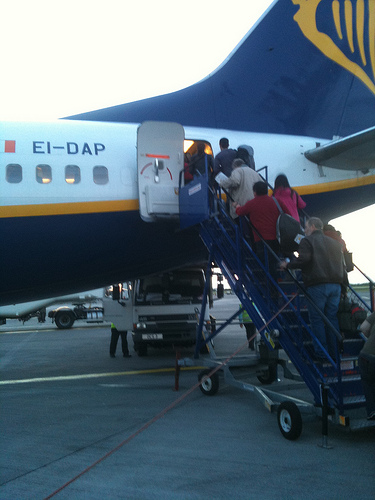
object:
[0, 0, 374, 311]
plane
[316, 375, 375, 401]
stairs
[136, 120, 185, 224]
door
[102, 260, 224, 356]
truck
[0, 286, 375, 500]
tarmac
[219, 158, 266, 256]
passenger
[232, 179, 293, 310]
person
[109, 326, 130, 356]
pants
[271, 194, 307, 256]
bag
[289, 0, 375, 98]
logo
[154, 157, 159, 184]
handle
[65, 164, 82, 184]
window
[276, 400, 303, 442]
wheel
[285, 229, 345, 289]
jacket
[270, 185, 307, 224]
coat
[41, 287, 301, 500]
cord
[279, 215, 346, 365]
man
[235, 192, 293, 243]
sweater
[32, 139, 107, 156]
lettering